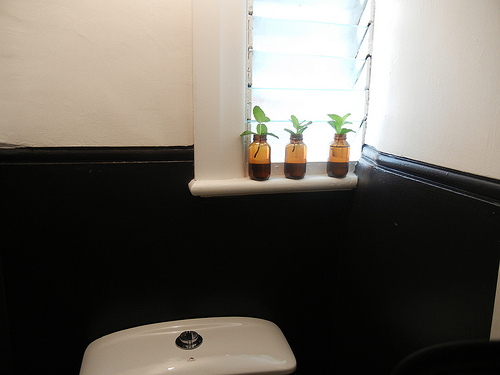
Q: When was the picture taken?
A: Daytime.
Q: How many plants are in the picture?
A: Three.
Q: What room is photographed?
A: Bathroom.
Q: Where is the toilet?
A: Bottom of the picture.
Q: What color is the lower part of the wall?
A: Black.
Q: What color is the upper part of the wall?
A: White.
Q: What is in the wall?
A: A window.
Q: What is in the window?
A: Plants.